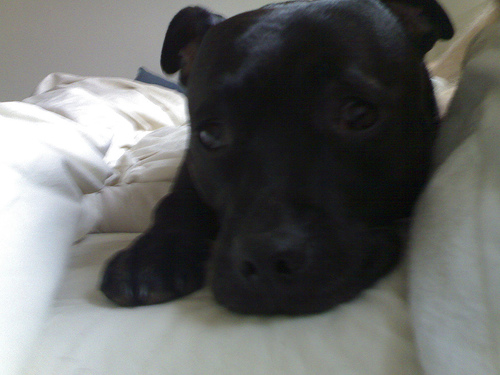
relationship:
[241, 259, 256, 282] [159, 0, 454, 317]
nostril on face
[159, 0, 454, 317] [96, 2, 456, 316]
face on dog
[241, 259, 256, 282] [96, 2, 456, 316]
nostril of dog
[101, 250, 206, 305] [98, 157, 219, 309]
paw on foot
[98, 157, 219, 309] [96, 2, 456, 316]
foot of dog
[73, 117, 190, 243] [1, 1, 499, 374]
crease on bed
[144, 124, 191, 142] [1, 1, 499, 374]
crease on bed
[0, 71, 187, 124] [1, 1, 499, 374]
edge of bed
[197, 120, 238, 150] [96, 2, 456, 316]
eye of dog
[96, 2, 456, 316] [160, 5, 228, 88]
dog has ear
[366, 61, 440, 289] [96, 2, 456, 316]
side of face of dog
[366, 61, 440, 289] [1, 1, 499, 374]
side of face resting on bed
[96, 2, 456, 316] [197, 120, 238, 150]
dog has eye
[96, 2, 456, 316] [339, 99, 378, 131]
dog has eye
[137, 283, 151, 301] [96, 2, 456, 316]
nail of dog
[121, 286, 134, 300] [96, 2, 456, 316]
nail of dog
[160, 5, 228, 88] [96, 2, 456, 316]
ear of dog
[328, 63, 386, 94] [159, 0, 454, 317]
puppy eyebrow lighter than face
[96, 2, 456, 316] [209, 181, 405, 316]
dog has muzzle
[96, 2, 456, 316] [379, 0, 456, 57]
dog has ear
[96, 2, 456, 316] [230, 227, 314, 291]
dog has nose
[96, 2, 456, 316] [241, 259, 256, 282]
dog has nostril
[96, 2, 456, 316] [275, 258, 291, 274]
dog has nostril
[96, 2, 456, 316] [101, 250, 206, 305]
dog has paw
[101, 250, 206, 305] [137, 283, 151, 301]
paw has nail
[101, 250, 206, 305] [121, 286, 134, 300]
paw has nail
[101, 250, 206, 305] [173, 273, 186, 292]
paw has nail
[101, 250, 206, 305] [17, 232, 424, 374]
paw resting on sheet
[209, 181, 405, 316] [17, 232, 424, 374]
muzzle resting on sheet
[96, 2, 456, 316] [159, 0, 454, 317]
dog has face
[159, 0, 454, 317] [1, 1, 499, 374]
face resting on bed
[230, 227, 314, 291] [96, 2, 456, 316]
nose of dog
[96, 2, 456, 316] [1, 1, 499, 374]
dog in bed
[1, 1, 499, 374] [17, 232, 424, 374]
bed with sheet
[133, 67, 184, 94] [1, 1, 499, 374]
pillow on bed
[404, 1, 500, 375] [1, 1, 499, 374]
pillow on bed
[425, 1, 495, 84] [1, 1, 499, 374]
pillow on bed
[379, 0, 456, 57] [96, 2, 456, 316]
ear of dog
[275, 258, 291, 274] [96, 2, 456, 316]
nostril of dog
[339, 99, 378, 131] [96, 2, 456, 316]
eye of dog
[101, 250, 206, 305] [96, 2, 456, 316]
paw of dog